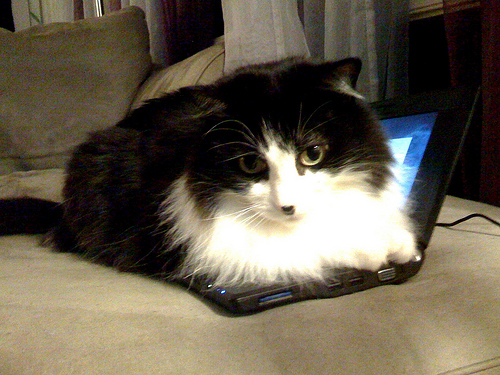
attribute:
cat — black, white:
[0, 55, 419, 287]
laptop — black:
[178, 85, 481, 316]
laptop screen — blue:
[370, 109, 441, 200]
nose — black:
[281, 203, 296, 214]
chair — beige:
[1, 185, 499, 374]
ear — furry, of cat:
[184, 82, 229, 116]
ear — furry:
[318, 56, 363, 102]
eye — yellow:
[233, 149, 270, 175]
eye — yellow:
[294, 141, 329, 164]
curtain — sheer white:
[221, 0, 414, 103]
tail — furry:
[0, 197, 69, 236]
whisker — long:
[197, 201, 264, 225]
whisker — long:
[302, 114, 340, 148]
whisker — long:
[198, 117, 258, 144]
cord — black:
[435, 211, 499, 232]